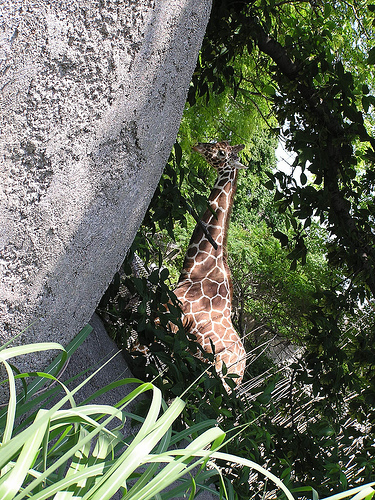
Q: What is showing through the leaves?
A: A bit of sky.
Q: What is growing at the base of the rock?
A: Green plant.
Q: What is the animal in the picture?
A: A giraffe.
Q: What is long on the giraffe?
A: The neck.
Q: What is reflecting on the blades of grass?
A: The sun.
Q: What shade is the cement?
A: Grey.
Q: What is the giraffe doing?
A: Grazing.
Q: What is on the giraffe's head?
A: Horns.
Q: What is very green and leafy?
A: The vegetation.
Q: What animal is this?
A: A giraffe.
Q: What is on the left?
A: A stone rock.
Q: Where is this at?
A: A forest.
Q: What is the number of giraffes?
A: 1.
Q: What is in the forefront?
A: Grass.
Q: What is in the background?
A: Trees.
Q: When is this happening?
A: During the day time.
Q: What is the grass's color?
A: Green.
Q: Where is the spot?
A: On the giraffe.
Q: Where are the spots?
A: On the giraffe.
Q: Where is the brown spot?
A: On the giraffe.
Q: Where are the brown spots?
A: On the giraffe.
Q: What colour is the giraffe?
A: Brown.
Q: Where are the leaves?
A: On the trees.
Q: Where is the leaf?
A: On the tree.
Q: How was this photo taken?
A: At angle.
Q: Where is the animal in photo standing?
A: In foliage.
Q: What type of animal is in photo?
A: Giraffe.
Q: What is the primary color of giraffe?
A: Brown.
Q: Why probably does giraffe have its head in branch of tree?
A: Eating.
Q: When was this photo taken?
A: Daytime.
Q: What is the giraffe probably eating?
A: Leaves.